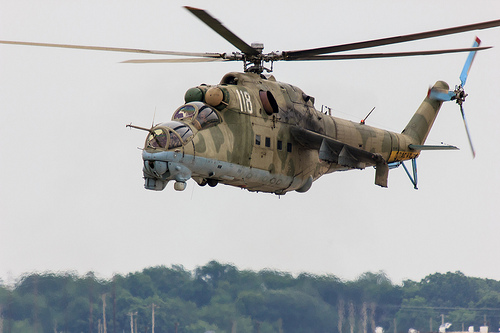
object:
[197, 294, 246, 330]
tree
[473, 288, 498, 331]
tree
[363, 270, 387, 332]
tree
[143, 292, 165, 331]
tree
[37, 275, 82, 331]
tree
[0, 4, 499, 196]
army helicopter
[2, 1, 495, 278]
air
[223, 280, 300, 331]
tree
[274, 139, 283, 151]
windows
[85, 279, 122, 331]
tree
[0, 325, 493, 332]
ground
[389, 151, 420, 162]
yellow paint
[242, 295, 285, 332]
tall hedges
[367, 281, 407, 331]
tree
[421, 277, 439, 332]
tree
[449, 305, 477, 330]
trees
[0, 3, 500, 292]
clouds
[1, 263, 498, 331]
background